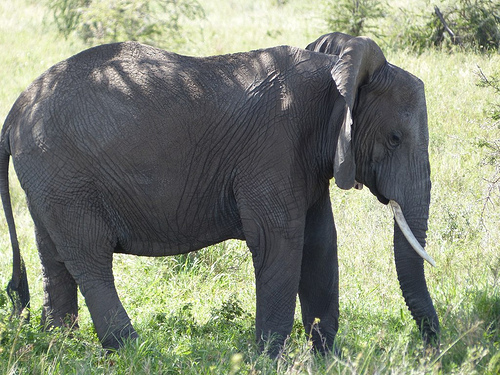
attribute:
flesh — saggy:
[183, 107, 255, 227]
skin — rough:
[86, 103, 249, 228]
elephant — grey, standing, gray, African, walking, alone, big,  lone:
[0, 32, 446, 358]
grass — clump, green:
[11, 3, 498, 374]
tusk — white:
[386, 197, 442, 269]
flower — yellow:
[309, 315, 325, 330]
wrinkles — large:
[44, 57, 427, 289]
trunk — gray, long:
[392, 201, 445, 339]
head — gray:
[342, 49, 448, 350]